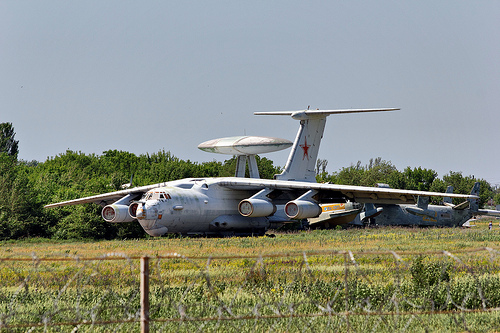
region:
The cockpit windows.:
[139, 190, 171, 201]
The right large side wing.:
[220, 173, 475, 205]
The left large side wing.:
[41, 179, 166, 209]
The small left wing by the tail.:
[256, 112, 298, 115]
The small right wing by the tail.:
[319, 109, 400, 111]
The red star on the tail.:
[297, 134, 314, 159]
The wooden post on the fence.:
[140, 254, 150, 331]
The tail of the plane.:
[284, 105, 326, 179]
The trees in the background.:
[5, 128, 493, 230]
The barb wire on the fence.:
[7, 253, 491, 331]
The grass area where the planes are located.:
[3, 235, 498, 327]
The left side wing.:
[34, 167, 180, 215]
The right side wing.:
[227, 172, 474, 207]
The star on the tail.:
[298, 140, 310, 157]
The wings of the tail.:
[259, 103, 397, 118]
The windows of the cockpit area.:
[145, 191, 169, 196]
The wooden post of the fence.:
[136, 253, 155, 332]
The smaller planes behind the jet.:
[305, 170, 490, 227]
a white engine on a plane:
[101, 196, 133, 224]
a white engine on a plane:
[127, 196, 146, 218]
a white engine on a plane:
[237, 185, 274, 220]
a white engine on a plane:
[287, 186, 321, 219]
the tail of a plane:
[257, 104, 394, 178]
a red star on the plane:
[298, 134, 313, 161]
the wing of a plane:
[40, 174, 197, 228]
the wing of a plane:
[225, 173, 477, 218]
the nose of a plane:
[137, 183, 194, 228]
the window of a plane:
[157, 191, 164, 202]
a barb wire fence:
[3, 245, 497, 331]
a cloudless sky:
[5, 5, 499, 103]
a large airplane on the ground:
[38, 101, 474, 240]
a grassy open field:
[11, 239, 498, 251]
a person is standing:
[483, 217, 497, 233]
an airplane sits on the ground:
[357, 182, 497, 234]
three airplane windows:
[156, 190, 176, 202]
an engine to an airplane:
[283, 192, 325, 222]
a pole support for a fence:
[134, 250, 153, 332]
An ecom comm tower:
[193, 132, 293, 158]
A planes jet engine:
[230, 194, 277, 215]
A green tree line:
[0, 117, 497, 232]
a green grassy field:
[0, 235, 498, 287]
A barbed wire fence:
[0, 243, 499, 328]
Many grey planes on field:
[38, 108, 495, 243]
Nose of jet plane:
[124, 183, 180, 233]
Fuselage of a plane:
[170, 185, 252, 232]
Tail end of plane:
[243, 97, 412, 171]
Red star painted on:
[299, 135, 313, 167]